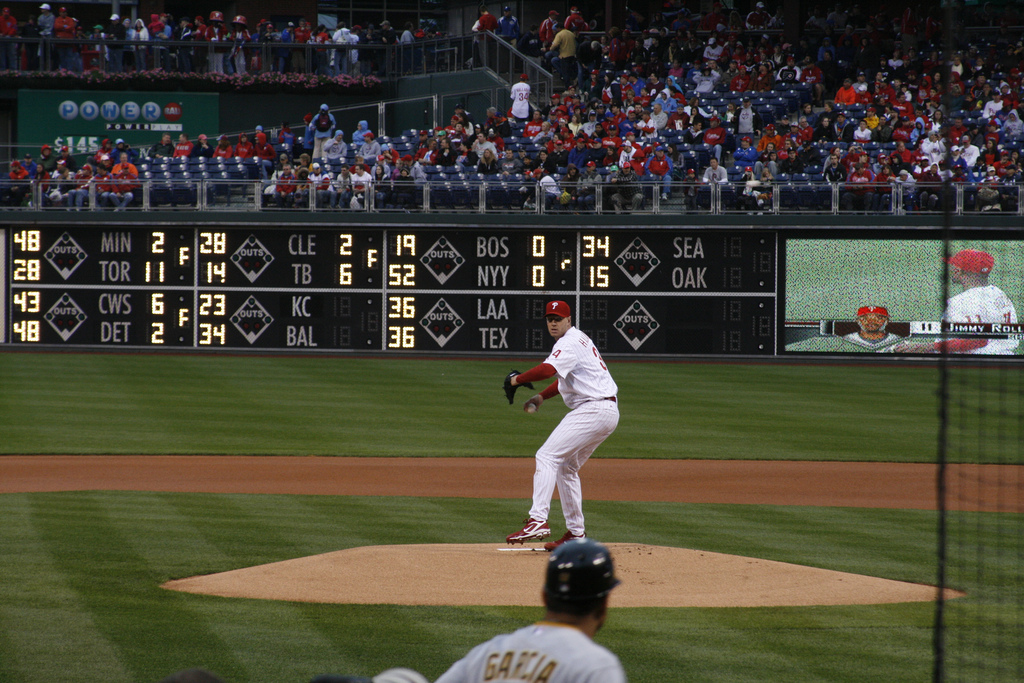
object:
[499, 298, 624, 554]
pitcher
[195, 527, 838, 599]
mound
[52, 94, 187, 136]
lottery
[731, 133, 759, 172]
fans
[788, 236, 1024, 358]
television screen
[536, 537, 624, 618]
helmet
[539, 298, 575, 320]
hat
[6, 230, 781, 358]
scoreboard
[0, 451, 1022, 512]
basepath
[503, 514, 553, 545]
foot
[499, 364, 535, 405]
glove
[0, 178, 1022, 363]
fence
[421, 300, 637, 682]
two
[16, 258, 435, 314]
wall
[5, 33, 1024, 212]
stands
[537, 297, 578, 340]
head